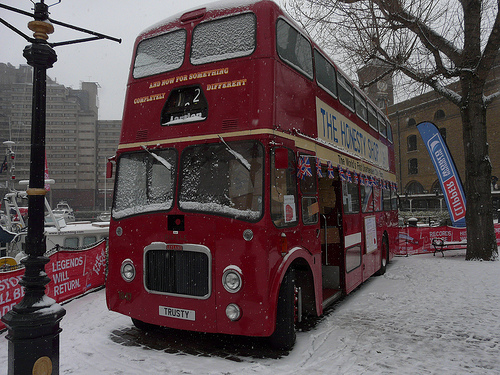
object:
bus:
[103, 0, 402, 351]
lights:
[119, 258, 136, 284]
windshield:
[111, 138, 265, 224]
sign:
[158, 305, 196, 322]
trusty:
[162, 307, 190, 318]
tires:
[373, 232, 388, 277]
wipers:
[214, 133, 250, 172]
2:
[191, 88, 200, 103]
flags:
[297, 154, 314, 181]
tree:
[281, 0, 498, 262]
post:
[0, 0, 125, 375]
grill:
[145, 249, 208, 296]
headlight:
[221, 268, 243, 294]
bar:
[322, 215, 329, 266]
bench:
[431, 237, 467, 257]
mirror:
[106, 157, 114, 178]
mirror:
[274, 142, 289, 169]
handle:
[316, 229, 321, 239]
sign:
[315, 95, 390, 171]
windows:
[188, 8, 261, 65]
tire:
[271, 265, 298, 351]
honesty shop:
[320, 108, 379, 162]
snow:
[0, 246, 500, 374]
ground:
[1, 248, 500, 373]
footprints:
[357, 315, 378, 329]